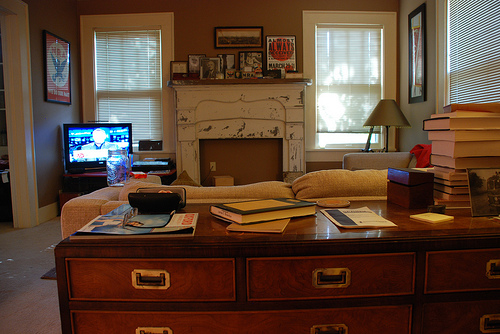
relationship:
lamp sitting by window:
[360, 95, 412, 150] [307, 15, 388, 148]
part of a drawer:
[234, 241, 395, 334] [291, 234, 412, 318]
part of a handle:
[286, 243, 369, 321] [302, 241, 376, 334]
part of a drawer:
[246, 257, 312, 301] [242, 249, 417, 301]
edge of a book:
[226, 177, 317, 264] [117, 169, 202, 243]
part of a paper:
[302, 201, 417, 251] [328, 202, 377, 235]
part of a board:
[84, 184, 284, 264] [247, 255, 419, 295]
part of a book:
[231, 178, 278, 245] [199, 155, 339, 254]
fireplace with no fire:
[171, 77, 311, 193] [192, 126, 292, 196]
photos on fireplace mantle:
[172, 62, 188, 79] [167, 78, 305, 181]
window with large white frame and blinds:
[316, 22, 384, 147] [314, 21, 381, 134]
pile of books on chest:
[187, 169, 357, 254] [55, 203, 499, 333]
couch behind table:
[61, 167, 433, 239] [128, 157, 379, 186]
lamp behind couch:
[363, 99, 411, 152] [145, 114, 396, 179]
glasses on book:
[116, 205, 183, 229] [70, 213, 199, 240]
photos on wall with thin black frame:
[172, 62, 188, 79] [42, 99, 59, 175]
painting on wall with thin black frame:
[411, 12, 421, 98] [256, 53, 299, 106]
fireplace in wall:
[171, 77, 311, 193] [18, 0, 437, 226]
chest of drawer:
[53, 202, 498, 332] [64, 255, 236, 302]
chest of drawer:
[53, 202, 498, 332] [242, 249, 417, 301]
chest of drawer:
[53, 202, 498, 332] [421, 245, 498, 294]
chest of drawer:
[53, 202, 498, 332] [67, 301, 412, 332]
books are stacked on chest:
[423, 104, 498, 217] [74, 210, 499, 315]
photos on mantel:
[166, 60, 191, 87] [161, 72, 316, 97]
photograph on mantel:
[189, 55, 205, 73] [161, 72, 316, 97]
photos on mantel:
[200, 55, 223, 82] [161, 72, 316, 97]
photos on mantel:
[213, 51, 241, 80] [161, 72, 316, 97]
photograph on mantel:
[239, 53, 262, 77] [161, 72, 316, 97]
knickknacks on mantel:
[266, 63, 305, 80] [161, 72, 316, 97]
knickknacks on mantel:
[263, 32, 300, 72] [161, 72, 316, 97]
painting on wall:
[386, 5, 436, 108] [273, 15, 295, 25]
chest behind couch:
[55, 203, 499, 333] [61, 168, 434, 240]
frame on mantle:
[266, 35, 297, 71] [170, 70, 319, 198]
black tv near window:
[63, 123, 132, 174] [78, 11, 175, 163]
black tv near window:
[63, 123, 132, 174] [300, 10, 400, 160]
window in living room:
[95, 30, 164, 152] [3, 3, 495, 328]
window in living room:
[316, 22, 384, 147] [3, 3, 495, 328]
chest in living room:
[55, 203, 499, 333] [3, 3, 495, 328]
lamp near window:
[363, 99, 411, 152] [299, 1, 389, 147]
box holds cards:
[385, 167, 433, 209] [412, 210, 454, 223]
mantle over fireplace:
[170, 76, 310, 138] [199, 138, 281, 187]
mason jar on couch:
[104, 143, 135, 188] [50, 156, 477, 248]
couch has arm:
[50, 156, 477, 248] [63, 169, 165, 203]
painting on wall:
[411, 12, 421, 98] [378, 93, 442, 153]